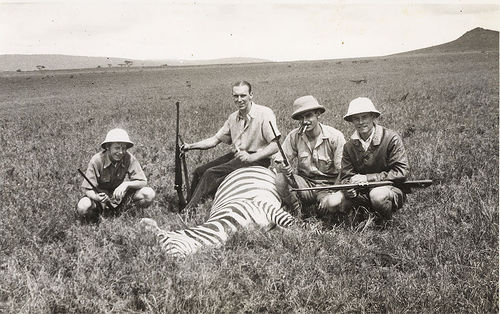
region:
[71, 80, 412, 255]
four people out in the wild hunting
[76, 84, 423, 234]
four people out in the wild hunting a zebra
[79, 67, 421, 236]
four people out in the wild hunting an animal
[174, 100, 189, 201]
a rifle held by a man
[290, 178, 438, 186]
a rifle held by a man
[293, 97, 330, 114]
man wearing a white hat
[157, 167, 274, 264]
a zebra on the ground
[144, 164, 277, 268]
a black and white zebra on the ground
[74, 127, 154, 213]
a man crouching on the field with a rifle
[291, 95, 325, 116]
a safari hat on his head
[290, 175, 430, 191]
a gun on the man's leg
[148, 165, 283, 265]
the zebra is dead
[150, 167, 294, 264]
the zebra is laying on the ground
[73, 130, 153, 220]
a boy squatting down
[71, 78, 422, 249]
four men sitting by a zebra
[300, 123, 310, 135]
a cigar in the man's mouth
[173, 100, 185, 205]
the rifle is standing up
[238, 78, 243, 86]
middle part in the man's hair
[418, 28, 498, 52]
a mountain in the distance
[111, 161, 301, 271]
this is a zebra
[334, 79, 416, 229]
this is a person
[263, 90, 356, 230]
this is a person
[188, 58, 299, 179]
this is a person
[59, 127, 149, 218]
this is a person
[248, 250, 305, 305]
the grass is long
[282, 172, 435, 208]
this is a gun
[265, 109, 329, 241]
this is a gun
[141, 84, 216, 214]
this is a gun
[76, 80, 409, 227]
the men in a field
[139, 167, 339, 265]
the zebra lying down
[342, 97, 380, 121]
the hat on the man's head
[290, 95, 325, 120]
the hat on the man's head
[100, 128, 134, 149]
the hat on the man's head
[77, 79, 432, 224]
the men posing with guns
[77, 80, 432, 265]
the men posing with guns and the dead zebra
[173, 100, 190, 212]
the gun standing up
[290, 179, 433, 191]
the gun across the man's lap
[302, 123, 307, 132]
the cigarette in the man's mouth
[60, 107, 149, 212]
Man holding a gun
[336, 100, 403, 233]
Man holding a gun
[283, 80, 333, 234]
Man holding a gun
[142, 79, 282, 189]
Man holding a gun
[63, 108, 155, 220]
Man in a field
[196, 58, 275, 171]
Man in a field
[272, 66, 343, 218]
Man in a field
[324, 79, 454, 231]
Man in a field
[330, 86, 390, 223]
Man wearing a hat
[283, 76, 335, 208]
Man wearing a hat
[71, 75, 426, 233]
Men gathered around zebra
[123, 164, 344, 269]
zebra dead in the grass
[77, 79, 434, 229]
men holding hunting rifles squatting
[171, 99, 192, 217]
rifle is being held by sling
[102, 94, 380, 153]
hats are safari hats